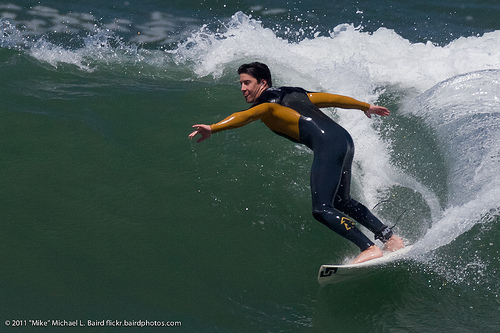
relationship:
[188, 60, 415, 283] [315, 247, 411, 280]
surfer in board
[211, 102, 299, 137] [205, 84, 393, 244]
panels in wetsuit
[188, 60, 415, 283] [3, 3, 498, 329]
surfer in water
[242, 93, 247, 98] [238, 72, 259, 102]
tongue in face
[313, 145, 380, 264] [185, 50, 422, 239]
leg of surfer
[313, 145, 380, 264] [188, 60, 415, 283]
leg of surfer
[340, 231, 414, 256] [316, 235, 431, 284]
feet on surfboard